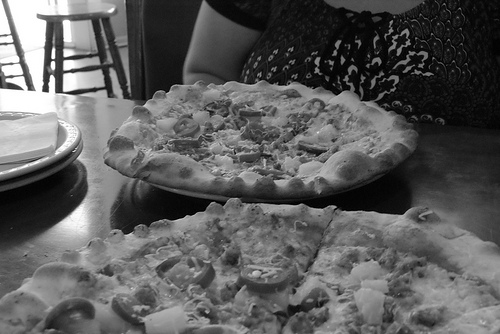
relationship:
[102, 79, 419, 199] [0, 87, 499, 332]
pizza on table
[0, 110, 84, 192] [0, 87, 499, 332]
white plate on table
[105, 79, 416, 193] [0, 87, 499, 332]
pizza on table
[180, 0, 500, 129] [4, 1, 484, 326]
lady in kitchen